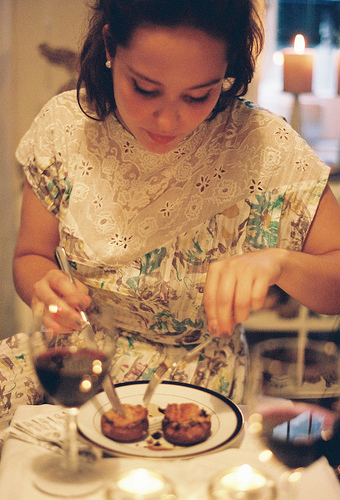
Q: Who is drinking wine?
A: Woman in dress.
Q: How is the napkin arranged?
A: Folded on table.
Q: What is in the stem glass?
A: Red wine.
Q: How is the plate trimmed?
A: Black and gold circumference.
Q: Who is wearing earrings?
A: Woman at table.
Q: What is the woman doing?
A: Cutting food.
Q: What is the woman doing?
A: Cutting food at dining table.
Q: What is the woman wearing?
A: Dress.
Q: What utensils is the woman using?
A: Knife and fork.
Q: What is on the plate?
A: Food.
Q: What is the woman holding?
A: Knife and fork.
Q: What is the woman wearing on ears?
A: Earrings.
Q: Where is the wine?
A: In the glass.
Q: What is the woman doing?
A: Cutting the food.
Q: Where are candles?
A: Behind the woman.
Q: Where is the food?
A: On the plate.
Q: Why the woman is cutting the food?
A: To make it easier to eat.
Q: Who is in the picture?
A: A young woman.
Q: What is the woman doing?
A: Eating.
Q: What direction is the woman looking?
A: Down.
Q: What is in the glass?
A: Wine.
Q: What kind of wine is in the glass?
A: Red.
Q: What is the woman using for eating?
A: A fork and a knife.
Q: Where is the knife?
A: In the woman's right hand.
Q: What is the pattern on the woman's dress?
A: Flowers.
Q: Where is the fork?
A: In the woman's left hand.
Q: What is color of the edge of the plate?
A: Brown.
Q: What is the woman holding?
A: Knife and fork.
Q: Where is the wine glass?
A: By the plate.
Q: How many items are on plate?
A: Two.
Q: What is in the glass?
A: Wine.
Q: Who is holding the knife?
A: A Woman.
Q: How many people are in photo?
A: One.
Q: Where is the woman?
A: At a table.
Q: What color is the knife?
A: Silver.